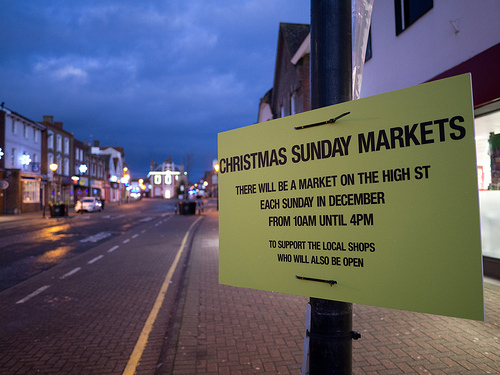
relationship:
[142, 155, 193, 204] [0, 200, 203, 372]
building at end of street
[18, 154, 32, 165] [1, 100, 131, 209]
lights on building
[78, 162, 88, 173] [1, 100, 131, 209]
lights on building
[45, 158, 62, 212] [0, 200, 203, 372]
light on street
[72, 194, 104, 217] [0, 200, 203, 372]
car on street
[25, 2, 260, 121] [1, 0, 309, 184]
clouds in sky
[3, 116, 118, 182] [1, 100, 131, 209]
windows in building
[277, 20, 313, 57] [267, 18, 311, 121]
roof of building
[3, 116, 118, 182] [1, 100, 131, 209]
windows on building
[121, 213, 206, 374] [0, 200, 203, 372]
line on street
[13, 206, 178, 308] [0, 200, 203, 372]
lines on street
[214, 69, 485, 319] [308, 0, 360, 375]
sign on light pole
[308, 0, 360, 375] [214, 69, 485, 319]
light pole behind sign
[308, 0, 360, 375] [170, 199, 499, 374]
light pole on sidewalk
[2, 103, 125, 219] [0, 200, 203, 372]
buildings on sides of street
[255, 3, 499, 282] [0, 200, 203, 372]
buildings on sides of street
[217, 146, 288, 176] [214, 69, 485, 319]
christmas on sign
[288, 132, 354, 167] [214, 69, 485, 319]
sunday on sign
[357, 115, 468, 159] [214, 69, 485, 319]
markets on sign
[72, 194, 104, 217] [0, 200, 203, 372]
car parked on street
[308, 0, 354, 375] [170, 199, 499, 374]
light pole on sidewalk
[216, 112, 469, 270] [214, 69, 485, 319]
letters on sign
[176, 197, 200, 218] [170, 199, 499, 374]
trash can on sidewalk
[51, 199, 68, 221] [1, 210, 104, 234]
trash can on sidewalk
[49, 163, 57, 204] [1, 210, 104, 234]
light on sidewalk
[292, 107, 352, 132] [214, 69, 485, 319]
zip tie on sign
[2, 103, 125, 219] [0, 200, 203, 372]
buildings by street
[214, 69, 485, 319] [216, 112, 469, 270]
sign with letters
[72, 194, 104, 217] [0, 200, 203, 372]
car on side of street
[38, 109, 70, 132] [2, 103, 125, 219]
chimney on buildings